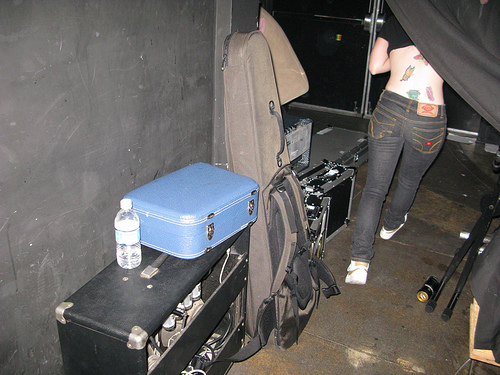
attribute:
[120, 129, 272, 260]
suitcase — blue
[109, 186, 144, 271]
bottle — water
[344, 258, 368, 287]
shoe — white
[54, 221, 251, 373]
case — black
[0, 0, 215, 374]
wall — Gray, black, grey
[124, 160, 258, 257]
suitcase — blue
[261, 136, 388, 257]
case — gray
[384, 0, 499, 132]
curtain — black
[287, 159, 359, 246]
trunk — black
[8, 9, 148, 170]
wall — black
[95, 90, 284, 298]
suitcase — blue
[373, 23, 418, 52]
shirt — black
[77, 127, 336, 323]
case — large, brown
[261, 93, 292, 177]
handle — black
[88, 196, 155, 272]
bottle — water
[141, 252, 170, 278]
handle — BLACK, SILVER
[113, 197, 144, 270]
bottle — plastic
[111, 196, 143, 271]
bottle — water